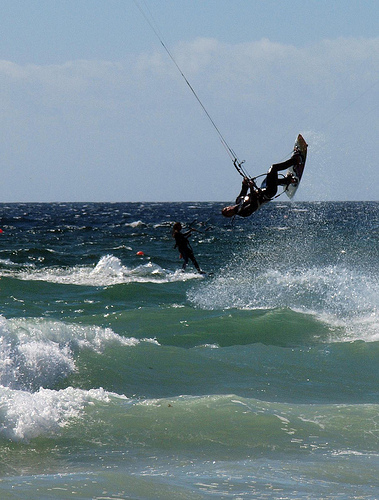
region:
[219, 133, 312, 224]
Man kite skiing on the air.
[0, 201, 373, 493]
Water in the forefront.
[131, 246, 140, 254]
Red buoy in the water.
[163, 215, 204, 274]
Person in the water.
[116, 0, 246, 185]
Cables attached to the man and board.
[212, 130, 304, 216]
Man wearing wet suit.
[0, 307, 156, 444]
White waves on the water.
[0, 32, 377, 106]
White clouds in the sky.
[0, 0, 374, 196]
Blue sky in the background.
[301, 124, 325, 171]
White splashes of water.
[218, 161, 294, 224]
this is a man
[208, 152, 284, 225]
the man is sea surfing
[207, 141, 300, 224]
the man is on air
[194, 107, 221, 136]
this is a rope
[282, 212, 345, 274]
the water is splashy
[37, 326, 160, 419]
these are the waves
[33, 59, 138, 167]
this is the sky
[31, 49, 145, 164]
the sky is grey in color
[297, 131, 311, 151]
this is the board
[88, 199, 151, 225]
this is the sea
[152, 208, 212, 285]
woman standing on the water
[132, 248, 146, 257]
buoy floating in the water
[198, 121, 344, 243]
person wakeboarding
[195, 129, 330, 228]
person in the air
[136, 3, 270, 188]
strings coming off the handlebar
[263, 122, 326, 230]
board is in the air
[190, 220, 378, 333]
droplets of water being kicked up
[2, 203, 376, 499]
large body of water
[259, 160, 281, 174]
knee is bent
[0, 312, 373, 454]
two waves in the water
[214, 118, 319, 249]
the kite surfer in the air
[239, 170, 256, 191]
the man holding the strings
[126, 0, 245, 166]
the strings to the kite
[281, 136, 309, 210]
the board strapped to the mans feet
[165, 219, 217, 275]
the person rides on the board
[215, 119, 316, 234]
the surfer upside down in mid air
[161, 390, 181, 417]
the weeds in the water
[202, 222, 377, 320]
the water splashing in the air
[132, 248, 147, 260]
the orange buoy in the water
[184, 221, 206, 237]
the person holding the handle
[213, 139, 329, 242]
the surfer is in the air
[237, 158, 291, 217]
the swimsuit is wet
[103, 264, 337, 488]
ripples are in the water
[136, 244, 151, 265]
the ball is red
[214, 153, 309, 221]
the man is upside down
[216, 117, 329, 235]
the man is being held by the rope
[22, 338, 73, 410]
the waves are white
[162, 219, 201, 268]
the person is in the sea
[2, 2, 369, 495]
the scene is outdoors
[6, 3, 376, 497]
photo was taken during the day